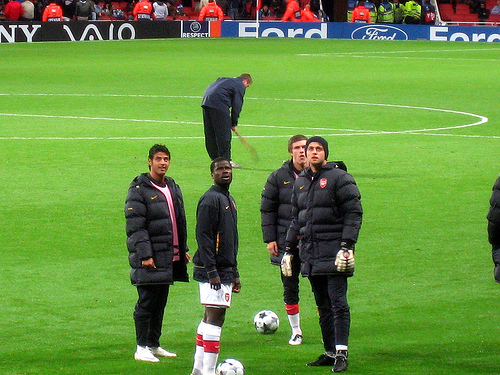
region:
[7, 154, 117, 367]
The grass is short and green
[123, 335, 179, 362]
The shoes of the man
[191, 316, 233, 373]
The man is wearing white socks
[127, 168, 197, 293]
The man is wearing a black bomber jacket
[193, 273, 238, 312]
The man is wearing white shorts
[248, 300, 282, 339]
The soccer ball on the ground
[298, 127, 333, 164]
The man is wearing a hat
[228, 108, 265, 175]
The man has a rake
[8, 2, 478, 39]
The people in the stands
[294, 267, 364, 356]
The man is wearing black pants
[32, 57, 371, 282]
the turf is green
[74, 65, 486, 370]
white lines are on the ground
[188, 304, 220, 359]
the socks are red and white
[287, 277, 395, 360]
the man is wearing black pants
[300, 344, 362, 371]
the man is wearig black shoes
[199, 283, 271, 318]
the man is wearing whtie shorts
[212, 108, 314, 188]
the man has a bat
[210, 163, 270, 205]
the man has a goatee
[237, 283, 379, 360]
a soccer ball is on the ground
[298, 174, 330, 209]
the man is wearing a nike jacket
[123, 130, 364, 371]
Four men standing on the soccer field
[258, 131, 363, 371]
Men wearing winter jackets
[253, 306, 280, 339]
White soccer ball with black stars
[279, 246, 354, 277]
Goalie gloves on man's hands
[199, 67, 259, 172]
Man sweeping field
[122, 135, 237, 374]
Men looking up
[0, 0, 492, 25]
People in the stands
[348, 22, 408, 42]
Ford logo on the fence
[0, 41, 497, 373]
Grass on the playing field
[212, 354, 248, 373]
Soccer ball by player's foot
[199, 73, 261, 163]
a man sweeping the field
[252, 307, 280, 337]
a black and white soccer ball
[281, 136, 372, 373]
a man in a puffy black coat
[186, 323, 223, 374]
a pair of tall white socks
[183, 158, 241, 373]
a man playing soccer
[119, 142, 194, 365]
a man in a puffy black coat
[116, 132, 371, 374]
a group of soccer players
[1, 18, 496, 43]
a banner of ads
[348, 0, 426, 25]
people in bright safety vests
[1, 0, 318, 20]
a crowd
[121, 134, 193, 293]
man wearing black coat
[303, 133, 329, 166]
man wearing black knit cap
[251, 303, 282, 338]
one black and white ball on grass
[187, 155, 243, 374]
man wearing long white and red socks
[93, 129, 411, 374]
four men looking up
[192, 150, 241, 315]
man wearing white shorts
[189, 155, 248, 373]
man standing next to white ball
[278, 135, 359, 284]
man wearing two big white gloves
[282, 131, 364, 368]
man wearing dark pants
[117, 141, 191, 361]
man wearing white sneakers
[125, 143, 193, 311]
man wearing black jacket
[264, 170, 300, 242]
man wearing black jacket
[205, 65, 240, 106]
man wearing black sweater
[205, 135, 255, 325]
man standing on the grass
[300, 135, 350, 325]
man standing on the grass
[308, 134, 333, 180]
man wearing cap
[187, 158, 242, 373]
The player is looking up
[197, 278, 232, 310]
The white shorts on the player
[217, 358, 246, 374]
The ball in front of the player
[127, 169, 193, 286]
The puffy jacket over the pink shirt